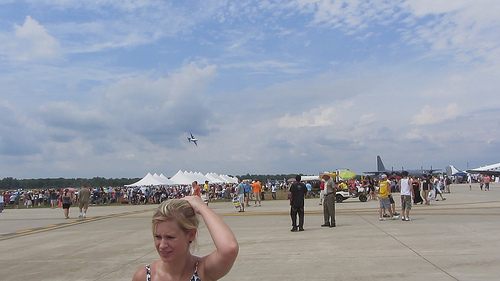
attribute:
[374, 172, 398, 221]
man — gray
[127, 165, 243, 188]
tents — white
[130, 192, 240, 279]
woman — white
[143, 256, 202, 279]
top — black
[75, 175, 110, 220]
outfit — khaki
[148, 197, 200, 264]
head — female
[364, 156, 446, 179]
plane — gray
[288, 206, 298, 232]
leg — pants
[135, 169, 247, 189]
tents — white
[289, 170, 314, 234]
man — distant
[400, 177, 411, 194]
shirt — white 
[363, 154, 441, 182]
parked airplane — gray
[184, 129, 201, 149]
blue sky — cloudy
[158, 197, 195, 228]
hair — blond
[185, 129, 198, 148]
plane — silver color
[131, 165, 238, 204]
tents — white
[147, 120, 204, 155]
airplane — airborne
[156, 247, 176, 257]
mouth — female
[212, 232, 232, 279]
elbow — caucasian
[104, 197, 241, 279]
person — blond, female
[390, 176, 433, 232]
man — caucasian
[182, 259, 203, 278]
shirt — strappy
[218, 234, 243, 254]
elbow — female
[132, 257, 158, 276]
shoulder — female's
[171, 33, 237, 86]
sky — blue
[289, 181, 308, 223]
shirt — black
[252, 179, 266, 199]
shirt — orange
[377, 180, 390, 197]
shirt — yellow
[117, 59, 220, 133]
clouds — white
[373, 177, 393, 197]
shirt — yellow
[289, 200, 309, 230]
pants — black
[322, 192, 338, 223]
pants — beige